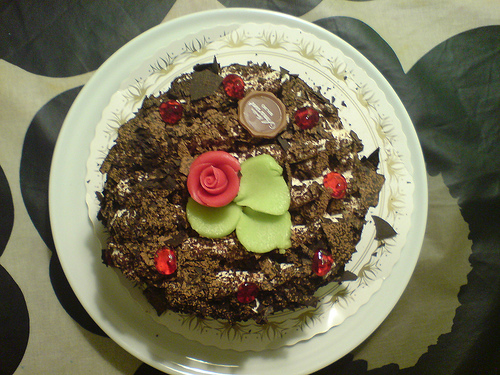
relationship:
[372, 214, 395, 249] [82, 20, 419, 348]
chocolate flake on top of doily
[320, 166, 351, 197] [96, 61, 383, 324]
candied cherry on top of cake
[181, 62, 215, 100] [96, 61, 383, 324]
chocolate shaving on top of cake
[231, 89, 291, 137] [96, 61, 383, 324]
brown disc on top of cake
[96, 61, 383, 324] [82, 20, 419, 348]
cake on top of doily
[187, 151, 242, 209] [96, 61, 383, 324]
candy flower on top of cake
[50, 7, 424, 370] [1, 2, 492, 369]
dessert plate on table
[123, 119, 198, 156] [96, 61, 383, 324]
brownie mixed into cake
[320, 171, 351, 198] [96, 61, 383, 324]
red flower on cake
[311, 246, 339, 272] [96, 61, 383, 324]
red flower on cake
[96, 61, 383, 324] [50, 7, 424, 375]
cake on a dessert plate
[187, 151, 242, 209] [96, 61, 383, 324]
candy flower on cake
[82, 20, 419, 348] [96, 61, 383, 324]
doily under cake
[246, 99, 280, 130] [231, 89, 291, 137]
writing on brown disc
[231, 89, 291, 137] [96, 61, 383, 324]
brown disc on cake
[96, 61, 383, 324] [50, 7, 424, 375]
cake on dessert plate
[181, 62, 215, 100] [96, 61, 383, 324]
chocolate shaving on cake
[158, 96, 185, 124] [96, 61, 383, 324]
candy on cake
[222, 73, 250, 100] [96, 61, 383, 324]
candy on cake